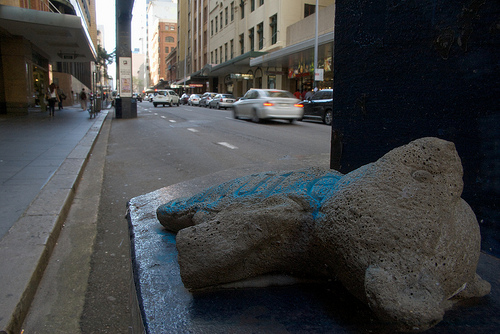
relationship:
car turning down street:
[153, 89, 181, 107] [143, 105, 248, 166]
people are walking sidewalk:
[34, 72, 105, 122] [13, 104, 83, 264]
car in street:
[232, 87, 305, 123] [152, 108, 234, 163]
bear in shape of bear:
[154, 137, 491, 334] [169, 133, 498, 304]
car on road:
[300, 85, 333, 124] [19, 95, 331, 332]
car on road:
[228, 85, 303, 121] [19, 95, 331, 332]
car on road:
[208, 95, 236, 109] [19, 95, 331, 332]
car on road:
[149, 87, 181, 106] [19, 95, 331, 332]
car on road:
[187, 94, 202, 105] [19, 95, 331, 332]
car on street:
[232, 87, 305, 123] [162, 120, 274, 162]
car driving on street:
[232, 87, 305, 123] [151, 112, 229, 166]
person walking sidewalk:
[45, 82, 58, 116] [8, 77, 108, 318]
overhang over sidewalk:
[9, 9, 121, 88] [0, 85, 110, 331]